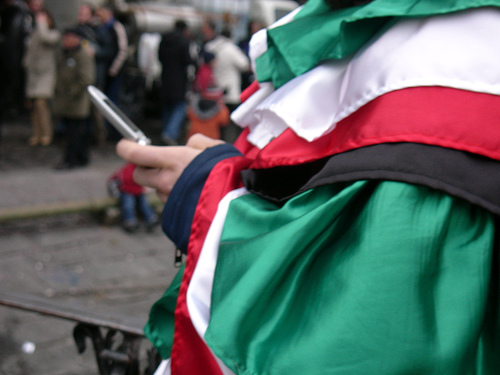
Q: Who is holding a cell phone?
A: A person.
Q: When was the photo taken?
A: Daytime.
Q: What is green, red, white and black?
A: A jacket.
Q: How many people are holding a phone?
A: One.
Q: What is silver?
A: A cell phone.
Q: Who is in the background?
A: People.